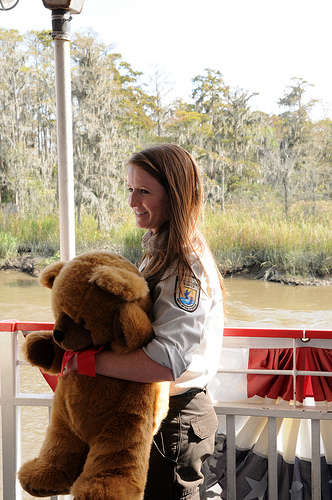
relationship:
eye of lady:
[126, 186, 133, 191] [60, 143, 227, 499]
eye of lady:
[138, 189, 148, 194] [60, 143, 227, 499]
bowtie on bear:
[57, 344, 102, 381] [21, 240, 157, 498]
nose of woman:
[128, 196, 140, 207] [62, 141, 227, 498]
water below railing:
[1, 276, 331, 498] [0, 320, 331, 498]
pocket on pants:
[186, 412, 233, 450] [143, 387, 220, 498]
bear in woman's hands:
[18, 244, 171, 499] [23, 327, 127, 383]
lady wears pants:
[60, 143, 227, 499] [151, 400, 216, 498]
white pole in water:
[51, 36, 78, 265] [0, 282, 327, 319]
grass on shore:
[282, 234, 294, 268] [224, 267, 321, 284]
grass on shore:
[237, 230, 241, 257] [224, 267, 321, 284]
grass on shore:
[250, 231, 259, 252] [224, 267, 321, 284]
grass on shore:
[268, 234, 276, 268] [224, 267, 321, 284]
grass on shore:
[304, 230, 309, 266] [224, 267, 321, 284]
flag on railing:
[201, 347, 330, 497] [0, 320, 331, 498]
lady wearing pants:
[60, 143, 227, 499] [156, 407, 210, 494]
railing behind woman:
[240, 314, 321, 456] [62, 141, 227, 498]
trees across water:
[2, 28, 58, 210] [222, 276, 330, 329]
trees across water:
[70, 28, 331, 229] [222, 276, 330, 329]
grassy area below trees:
[0, 201, 332, 287] [1, 26, 331, 232]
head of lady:
[111, 140, 220, 233] [60, 143, 227, 499]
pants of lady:
[158, 400, 234, 497] [60, 143, 227, 499]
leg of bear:
[70, 429, 151, 498] [21, 240, 157, 498]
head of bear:
[35, 251, 155, 352] [20, 250, 167, 499]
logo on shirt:
[174, 265, 201, 314] [134, 225, 224, 395]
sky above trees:
[1, 0, 330, 122] [1, 26, 331, 232]